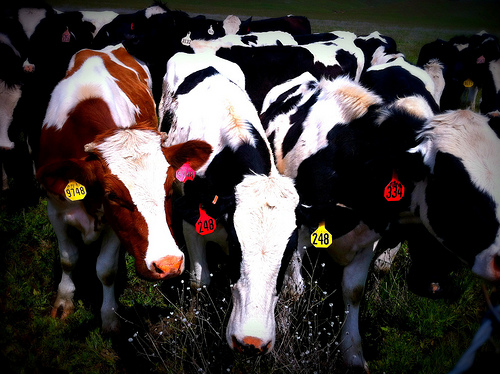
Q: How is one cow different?
A: It's brown.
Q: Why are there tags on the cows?
A: Identification.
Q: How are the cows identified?
A: Colored tags.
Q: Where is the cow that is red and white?
A: Far left.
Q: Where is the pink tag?
A: In the red cow's ear.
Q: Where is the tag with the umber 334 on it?
A: On the ear of the cow on the right.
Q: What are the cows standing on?
A: Grass.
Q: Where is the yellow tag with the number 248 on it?
A: Left ear of the middle cow.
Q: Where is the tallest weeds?
A: Under the head of the middle cow.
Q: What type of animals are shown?
A: Cows.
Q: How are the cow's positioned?
A: Standing.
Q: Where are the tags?
A: Cow's ears.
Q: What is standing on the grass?
A: Cows.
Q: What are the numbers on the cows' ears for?
A: To identify the cows easily.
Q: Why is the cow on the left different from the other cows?
A: Because she is the only one to be brown and white.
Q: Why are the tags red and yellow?
A: So that they can be identified easily.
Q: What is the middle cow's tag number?
A: Two forty-eight.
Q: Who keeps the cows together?
A: The farmer.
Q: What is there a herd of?
A: Cows.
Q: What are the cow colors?
A: Brown and white.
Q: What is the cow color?
A: Black and white.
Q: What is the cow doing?
A: Standing.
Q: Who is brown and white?
A: Cow on left.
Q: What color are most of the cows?
A: Black and white.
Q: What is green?
A: Grass.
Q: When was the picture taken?
A: Daytime.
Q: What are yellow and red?
A: Tags on cows.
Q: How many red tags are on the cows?
A: Three.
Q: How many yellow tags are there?
A: Two.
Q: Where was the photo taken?
A: At a farm.